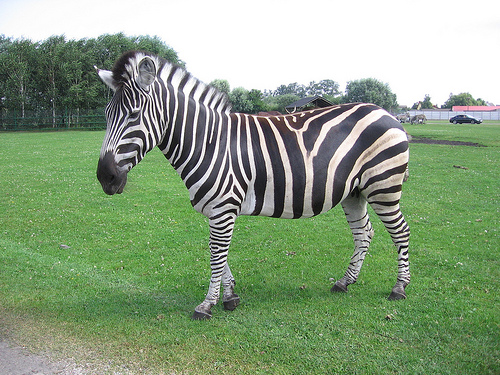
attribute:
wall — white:
[401, 101, 498, 126]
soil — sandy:
[405, 128, 497, 156]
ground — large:
[4, 118, 499, 372]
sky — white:
[3, 1, 498, 89]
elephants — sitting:
[394, 108, 436, 131]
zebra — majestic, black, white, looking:
[87, 43, 415, 323]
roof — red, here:
[448, 99, 500, 114]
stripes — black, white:
[199, 122, 328, 196]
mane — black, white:
[112, 47, 271, 120]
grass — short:
[49, 251, 165, 335]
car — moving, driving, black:
[442, 111, 487, 128]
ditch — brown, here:
[406, 133, 494, 147]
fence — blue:
[3, 103, 113, 134]